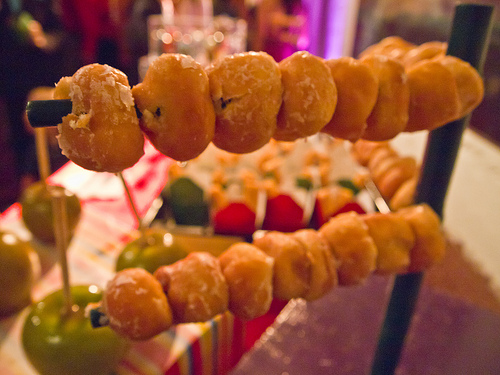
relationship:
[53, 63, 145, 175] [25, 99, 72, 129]
donut on black pole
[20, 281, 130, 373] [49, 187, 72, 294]
apple on stick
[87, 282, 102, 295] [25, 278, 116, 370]
light on apple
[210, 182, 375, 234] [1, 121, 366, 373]
red boxes on table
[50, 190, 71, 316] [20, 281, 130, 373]
candy apple in apple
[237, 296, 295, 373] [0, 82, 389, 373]
edge of table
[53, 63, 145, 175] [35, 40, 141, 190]
donut on side of donut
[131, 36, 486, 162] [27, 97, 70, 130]
donut holes on black pole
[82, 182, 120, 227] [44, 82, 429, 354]
light on table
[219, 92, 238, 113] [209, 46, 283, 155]
hole in doughnut